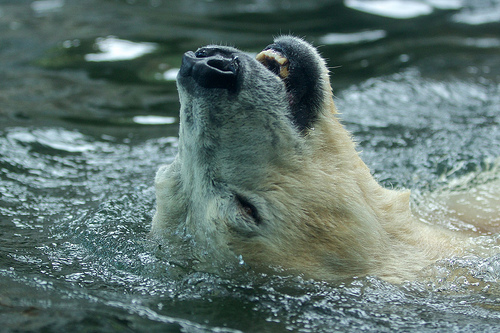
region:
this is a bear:
[139, 14, 495, 326]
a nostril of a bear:
[201, 52, 246, 87]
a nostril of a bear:
[188, 42, 215, 57]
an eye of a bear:
[219, 180, 277, 240]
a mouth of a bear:
[227, 25, 311, 105]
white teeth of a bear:
[251, 39, 291, 77]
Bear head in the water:
[151, 36, 483, 318]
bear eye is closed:
[221, 185, 267, 231]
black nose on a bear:
[183, 38, 245, 96]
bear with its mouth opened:
[175, 22, 335, 127]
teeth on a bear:
[256, 42, 294, 78]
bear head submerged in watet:
[154, 46, 386, 294]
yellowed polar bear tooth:
[278, 65, 290, 77]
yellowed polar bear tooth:
[276, 56, 286, 63]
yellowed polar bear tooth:
[271, 52, 281, 59]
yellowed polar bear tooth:
[263, 47, 271, 56]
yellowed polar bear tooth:
[266, 48, 276, 55]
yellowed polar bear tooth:
[256, 51, 265, 59]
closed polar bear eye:
[224, 182, 269, 229]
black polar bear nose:
[182, 43, 240, 93]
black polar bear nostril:
[205, 57, 235, 73]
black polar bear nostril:
[188, 43, 213, 60]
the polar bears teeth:
[258, 48, 282, 71]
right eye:
[233, 183, 265, 230]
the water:
[59, 250, 129, 312]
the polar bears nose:
[183, 50, 235, 74]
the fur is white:
[310, 171, 367, 248]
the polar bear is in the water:
[141, 35, 438, 280]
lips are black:
[293, 74, 314, 116]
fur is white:
[306, 198, 358, 249]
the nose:
[186, 47, 233, 74]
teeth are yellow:
[266, 47, 286, 63]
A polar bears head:
[158, 25, 409, 285]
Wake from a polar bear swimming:
[330, 50, 490, 115]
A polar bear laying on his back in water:
[135, 20, 492, 277]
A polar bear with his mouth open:
[150, 25, 411, 280]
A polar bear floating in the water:
[145, 30, 401, 266]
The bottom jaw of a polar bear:
[255, 25, 335, 125]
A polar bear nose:
[170, 35, 285, 155]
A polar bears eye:
[220, 180, 275, 245]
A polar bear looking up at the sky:
[147, 35, 379, 276]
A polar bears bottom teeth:
[252, 47, 294, 80]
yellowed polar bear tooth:
[275, 55, 290, 65]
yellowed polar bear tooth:
[268, 49, 274, 56]